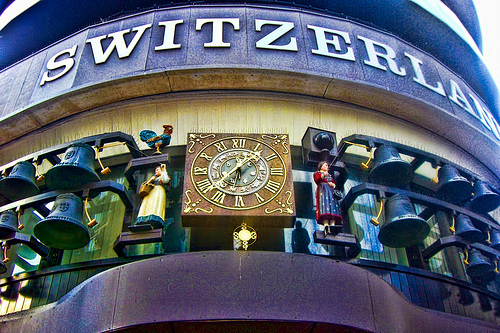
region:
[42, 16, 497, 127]
the word Switzerland on the side of a building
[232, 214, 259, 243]
a yellow light on the front of a building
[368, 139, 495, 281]
a group of black bells on the side of a building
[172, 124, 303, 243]
a bronze colored clock on the face of a building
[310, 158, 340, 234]
a figure in a red and white dress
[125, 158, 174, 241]
a figure in a blue and tan dress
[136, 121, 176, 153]
a figure of a rooster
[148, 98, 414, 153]
the lit underside of a portion of a building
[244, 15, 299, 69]
the white letter Z on the front of a building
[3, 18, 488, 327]
the ornate facade of a building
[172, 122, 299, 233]
The clock is square.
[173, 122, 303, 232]
The clock is brown.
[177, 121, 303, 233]
Clock has Roman numerals.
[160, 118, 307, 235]
Roman numberals are gold.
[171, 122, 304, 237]
Clock hands are gold.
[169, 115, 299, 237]
The clock is ornate.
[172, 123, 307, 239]
Corner designs on clock are gold.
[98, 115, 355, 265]
A figure stands on each side of clock.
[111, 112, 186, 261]
Rooster stands above figure.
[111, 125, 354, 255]
Both figures are women.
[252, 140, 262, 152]
golden roman numeral one on a square clock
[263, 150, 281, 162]
golden roman numeral two on a brown clock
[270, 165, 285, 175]
golden roman numeral three on a clock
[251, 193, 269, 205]
golden roman numeral four on a clock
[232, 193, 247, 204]
roman numeral five on a square clock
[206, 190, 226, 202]
roman numeral six on a clock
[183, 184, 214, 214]
gold design on a square clock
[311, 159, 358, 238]
female figurine on display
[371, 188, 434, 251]
blue bell hanging on a building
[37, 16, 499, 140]
white text on a building reading Switzerland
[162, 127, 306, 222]
clock is gold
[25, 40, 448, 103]
white letters on blue background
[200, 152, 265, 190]
clock hands are gold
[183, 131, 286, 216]
background of clock is brown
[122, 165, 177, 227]
white woman statue next to clock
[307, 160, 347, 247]
blue and red woman statue near clock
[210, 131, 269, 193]
roman numerals on clock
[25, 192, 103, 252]
black bells next to clock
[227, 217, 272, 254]
gold pendulum under clock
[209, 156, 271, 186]
grey center to clock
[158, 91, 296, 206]
big clock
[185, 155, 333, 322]
big clock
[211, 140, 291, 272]
big clock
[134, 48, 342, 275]
big clock